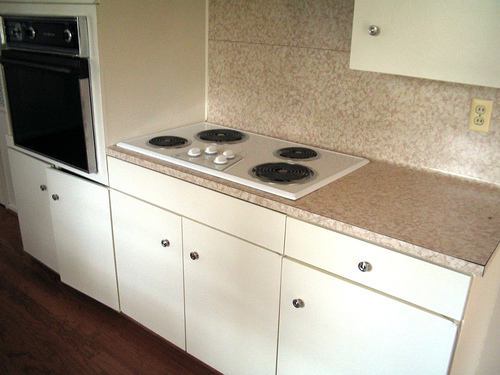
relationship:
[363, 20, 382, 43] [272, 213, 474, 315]
single knob to drawer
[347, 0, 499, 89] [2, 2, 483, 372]
cabinet in a kitchen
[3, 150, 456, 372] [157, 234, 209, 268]
cabinets have round silver knobs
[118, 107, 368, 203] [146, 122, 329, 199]
cook top with four burners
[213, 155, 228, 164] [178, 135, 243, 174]
dials on oven control burners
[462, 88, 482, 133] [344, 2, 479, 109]
outlet under cabinet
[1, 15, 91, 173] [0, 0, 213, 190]
black oven in wall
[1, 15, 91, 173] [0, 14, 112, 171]
black oven has black front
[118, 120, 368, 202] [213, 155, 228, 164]
cook top with dials on oven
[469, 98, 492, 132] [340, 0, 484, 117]
outlet under cabinet